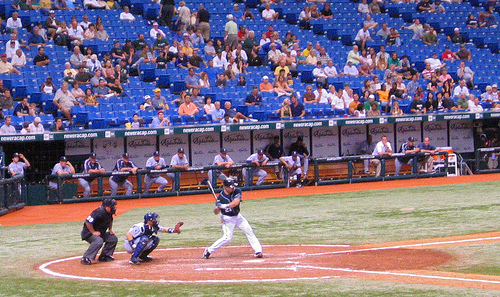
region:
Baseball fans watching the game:
[2, 24, 499, 135]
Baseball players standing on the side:
[8, 129, 498, 187]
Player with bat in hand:
[183, 166, 283, 268]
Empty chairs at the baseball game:
[83, 70, 150, 121]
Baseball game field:
[272, 198, 499, 290]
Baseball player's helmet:
[209, 165, 249, 193]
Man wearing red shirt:
[436, 36, 462, 66]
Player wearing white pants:
[196, 202, 276, 272]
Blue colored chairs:
[80, 100, 125, 125]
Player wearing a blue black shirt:
[205, 182, 246, 218]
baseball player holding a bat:
[186, 162, 266, 267]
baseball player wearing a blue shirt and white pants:
[195, 175, 262, 260]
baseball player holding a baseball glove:
[121, 192, 196, 257]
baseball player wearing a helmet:
[122, 190, 192, 266]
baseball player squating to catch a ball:
[120, 201, 187, 273]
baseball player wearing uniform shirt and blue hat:
[170, 142, 202, 199]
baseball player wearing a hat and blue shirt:
[75, 149, 117, 193]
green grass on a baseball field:
[332, 185, 487, 234]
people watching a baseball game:
[293, 76, 404, 106]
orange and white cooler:
[430, 138, 458, 166]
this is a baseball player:
[199, 162, 256, 262]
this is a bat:
[207, 177, 218, 212]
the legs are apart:
[206, 220, 257, 257]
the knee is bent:
[217, 232, 229, 241]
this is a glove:
[172, 219, 184, 232]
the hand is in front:
[162, 217, 189, 235]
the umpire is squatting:
[78, 193, 118, 256]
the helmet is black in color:
[224, 177, 234, 184]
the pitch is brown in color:
[315, 247, 375, 270]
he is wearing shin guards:
[136, 235, 156, 259]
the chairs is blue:
[83, 57, 275, 135]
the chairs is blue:
[112, 47, 322, 162]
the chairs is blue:
[139, 25, 270, 112]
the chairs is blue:
[165, 60, 307, 145]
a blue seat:
[87, 115, 107, 128]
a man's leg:
[235, 218, 265, 250]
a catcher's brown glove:
[170, 219, 187, 234]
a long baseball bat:
[206, 172, 221, 199]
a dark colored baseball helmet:
[220, 175, 240, 185]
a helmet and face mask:
[143, 211, 161, 226]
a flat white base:
[232, 251, 267, 258]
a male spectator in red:
[438, 43, 453, 55]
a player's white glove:
[216, 202, 228, 207]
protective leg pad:
[131, 237, 153, 255]